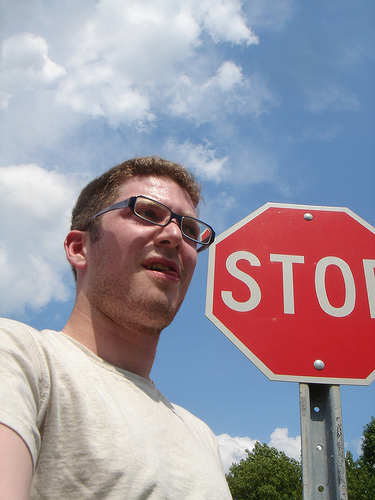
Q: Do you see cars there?
A: No, there are no cars.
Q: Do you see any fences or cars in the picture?
A: No, there are no cars or fences.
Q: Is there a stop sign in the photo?
A: Yes, there is a stop sign.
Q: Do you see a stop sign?
A: Yes, there is a stop sign.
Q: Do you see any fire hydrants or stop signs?
A: Yes, there is a stop sign.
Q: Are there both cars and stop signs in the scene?
A: No, there is a stop sign but no cars.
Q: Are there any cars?
A: No, there are no cars.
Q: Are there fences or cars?
A: No, there are no cars or fences.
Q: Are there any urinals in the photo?
A: No, there are no urinals.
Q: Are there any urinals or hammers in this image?
A: No, there are no urinals or hammers.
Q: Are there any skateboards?
A: No, there are no skateboards.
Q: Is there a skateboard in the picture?
A: No, there are no skateboards.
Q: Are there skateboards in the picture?
A: No, there are no skateboards.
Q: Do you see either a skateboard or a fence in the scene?
A: No, there are no skateboards or fences.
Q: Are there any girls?
A: No, there are no girls.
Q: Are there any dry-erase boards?
A: No, there are no dry-erase boards.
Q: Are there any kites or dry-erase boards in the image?
A: No, there are no dry-erase boards or kites.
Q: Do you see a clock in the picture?
A: No, there are no clocks.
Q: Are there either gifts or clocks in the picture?
A: No, there are no clocks or gifts.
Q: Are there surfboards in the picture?
A: No, there are no surfboards.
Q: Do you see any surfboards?
A: No, there are no surfboards.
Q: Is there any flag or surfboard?
A: No, there are no surfboards or flags.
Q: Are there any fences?
A: No, there are no fences.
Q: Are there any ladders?
A: No, there are no ladders.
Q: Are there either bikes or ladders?
A: No, there are no ladders or bikes.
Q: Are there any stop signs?
A: Yes, there is a stop sign.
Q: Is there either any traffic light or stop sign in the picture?
A: Yes, there is a stop sign.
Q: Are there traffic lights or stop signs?
A: Yes, there is a stop sign.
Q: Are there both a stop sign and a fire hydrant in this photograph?
A: No, there is a stop sign but no fire hydrants.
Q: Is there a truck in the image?
A: No, there are no trucks.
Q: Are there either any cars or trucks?
A: No, there are no trucks or cars.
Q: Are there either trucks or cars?
A: No, there are no trucks or cars.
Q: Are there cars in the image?
A: No, there are no cars.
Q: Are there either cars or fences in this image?
A: No, there are no cars or fences.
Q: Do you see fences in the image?
A: No, there are no fences.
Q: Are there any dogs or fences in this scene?
A: No, there are no fences or dogs.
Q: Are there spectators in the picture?
A: No, there are no spectators.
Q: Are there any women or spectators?
A: No, there are no spectators or women.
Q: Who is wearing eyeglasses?
A: The man is wearing eyeglasses.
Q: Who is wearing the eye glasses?
A: The man is wearing eyeglasses.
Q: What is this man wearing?
A: The man is wearing eyeglasses.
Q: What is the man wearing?
A: The man is wearing eyeglasses.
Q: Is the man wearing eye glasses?
A: Yes, the man is wearing eye glasses.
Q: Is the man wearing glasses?
A: No, the man is wearing eye glasses.